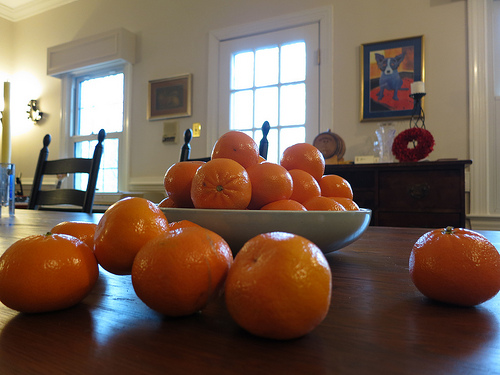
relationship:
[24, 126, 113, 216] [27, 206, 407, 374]
chair near table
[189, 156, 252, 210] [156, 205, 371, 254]
orange in bowl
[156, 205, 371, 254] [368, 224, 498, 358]
bowl on table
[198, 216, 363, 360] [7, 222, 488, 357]
oranges on table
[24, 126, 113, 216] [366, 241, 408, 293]
chair next table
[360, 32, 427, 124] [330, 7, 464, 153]
painting on wall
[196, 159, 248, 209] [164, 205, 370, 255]
orange in bowl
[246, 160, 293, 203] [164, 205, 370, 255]
orange in bowl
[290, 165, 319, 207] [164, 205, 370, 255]
orange in bowl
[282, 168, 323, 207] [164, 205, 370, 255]
orange in bowl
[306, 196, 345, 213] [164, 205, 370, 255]
orange in bowl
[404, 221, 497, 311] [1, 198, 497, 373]
orange on table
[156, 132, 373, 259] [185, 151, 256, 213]
bowl has orange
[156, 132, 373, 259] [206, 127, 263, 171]
bowl has orange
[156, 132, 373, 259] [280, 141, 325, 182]
bowl has orange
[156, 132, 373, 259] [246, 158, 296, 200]
bowl has orange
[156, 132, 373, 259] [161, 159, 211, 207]
bowl has orange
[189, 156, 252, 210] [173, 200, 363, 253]
orange in bowl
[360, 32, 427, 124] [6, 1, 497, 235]
painting on wall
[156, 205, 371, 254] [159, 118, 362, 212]
bowl of oranges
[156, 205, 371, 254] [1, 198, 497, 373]
bowl on table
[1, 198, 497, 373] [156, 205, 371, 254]
table has bowl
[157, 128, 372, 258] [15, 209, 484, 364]
oranges on table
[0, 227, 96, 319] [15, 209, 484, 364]
orange on table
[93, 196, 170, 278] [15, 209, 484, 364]
orange on table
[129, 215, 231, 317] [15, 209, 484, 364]
orange on table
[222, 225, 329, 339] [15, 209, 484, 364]
orange on table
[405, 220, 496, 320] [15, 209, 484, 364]
orange on table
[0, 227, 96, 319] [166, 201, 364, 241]
orange in bowl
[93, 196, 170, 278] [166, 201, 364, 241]
orange in bowl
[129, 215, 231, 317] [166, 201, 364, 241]
orange in bowl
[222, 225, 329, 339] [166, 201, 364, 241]
orange in bowl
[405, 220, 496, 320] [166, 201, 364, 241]
orange in bowl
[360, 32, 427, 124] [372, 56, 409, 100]
painting of dog